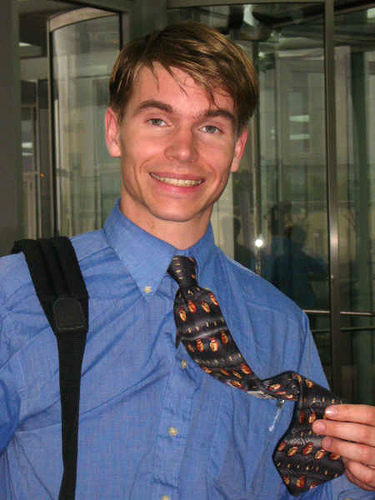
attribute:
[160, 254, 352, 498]
tie — designed, brown, silk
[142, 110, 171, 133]
eye — blue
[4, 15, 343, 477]
person — smiling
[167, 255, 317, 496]
tie — black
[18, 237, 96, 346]
strap — black, cushion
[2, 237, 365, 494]
shirt — blue, creased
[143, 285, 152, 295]
button — white, small, plastic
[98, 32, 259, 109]
hair — brown